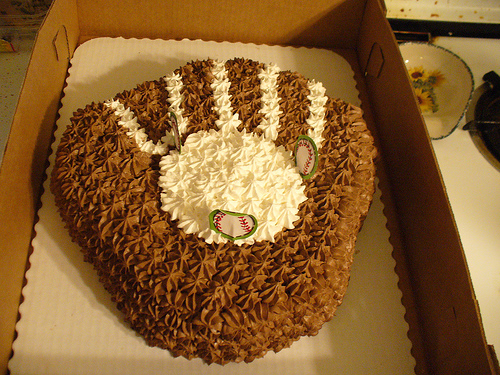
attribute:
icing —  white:
[103, 99, 162, 154]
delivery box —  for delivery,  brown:
[0, 0, 497, 373]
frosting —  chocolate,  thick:
[48, 56, 380, 367]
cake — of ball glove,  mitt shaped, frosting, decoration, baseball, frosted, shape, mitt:
[50, 54, 377, 366]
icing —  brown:
[177, 265, 245, 309]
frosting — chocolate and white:
[86, 114, 363, 310]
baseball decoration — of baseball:
[291, 134, 316, 180]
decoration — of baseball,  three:
[170, 109, 181, 150]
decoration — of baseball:
[291, 132, 321, 179]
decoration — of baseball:
[206, 207, 258, 239]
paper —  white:
[15, 22, 415, 374]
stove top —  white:
[442, 51, 496, 191]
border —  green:
[66, 33, 376, 348]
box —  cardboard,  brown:
[0, 2, 498, 374]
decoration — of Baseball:
[287, 133, 324, 179]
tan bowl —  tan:
[397, 38, 476, 133]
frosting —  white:
[157, 126, 307, 244]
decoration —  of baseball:
[290, 131, 318, 181]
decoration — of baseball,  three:
[169, 112, 319, 240]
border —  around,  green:
[311, 138, 317, 181]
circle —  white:
[156, 120, 310, 243]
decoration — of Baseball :
[209, 211, 257, 242]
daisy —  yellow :
[420, 65, 446, 90]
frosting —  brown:
[115, 246, 339, 359]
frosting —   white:
[212, 60, 237, 133]